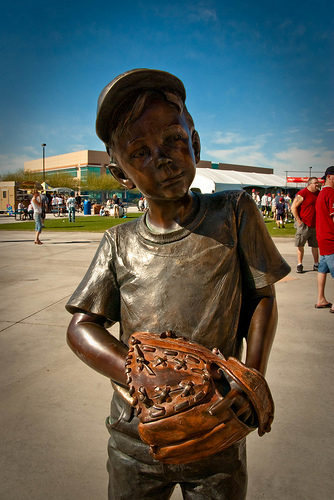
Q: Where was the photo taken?
A: Outddoors.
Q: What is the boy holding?
A: A mitten.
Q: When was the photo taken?
A: Day time.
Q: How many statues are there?
A: One.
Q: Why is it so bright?
A: Sunny.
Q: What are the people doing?
A: Walking.